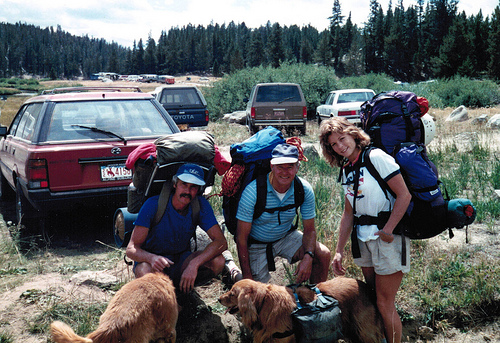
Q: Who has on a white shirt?
A: Female on right.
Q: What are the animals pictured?
A: Dogs.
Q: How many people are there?
A: Three.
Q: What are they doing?
A: Going hiking.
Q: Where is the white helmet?
A: On females backpack.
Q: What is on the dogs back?
A: Backpack.